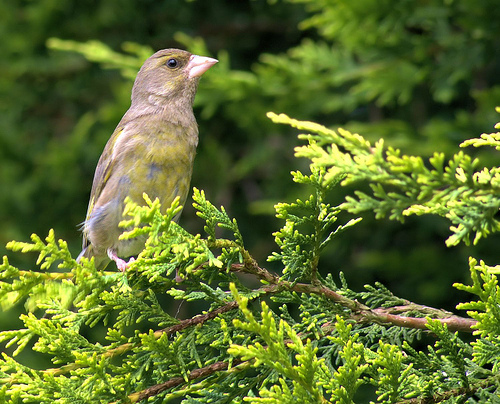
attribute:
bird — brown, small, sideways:
[72, 46, 222, 267]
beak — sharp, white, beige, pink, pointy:
[189, 51, 219, 78]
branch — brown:
[312, 263, 487, 342]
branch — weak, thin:
[159, 286, 275, 337]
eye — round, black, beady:
[164, 56, 177, 68]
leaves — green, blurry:
[46, 1, 499, 126]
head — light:
[130, 46, 219, 106]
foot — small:
[106, 247, 134, 271]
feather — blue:
[77, 203, 116, 232]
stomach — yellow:
[134, 126, 192, 212]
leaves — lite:
[2, 110, 499, 403]